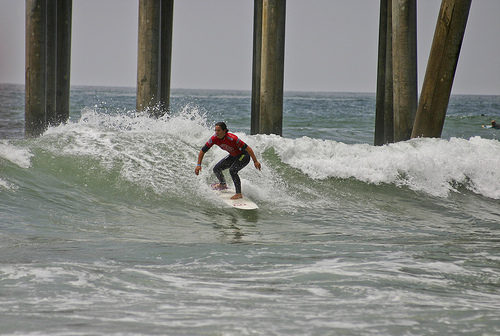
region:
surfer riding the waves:
[8, 8, 470, 298]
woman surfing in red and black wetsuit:
[164, 80, 299, 247]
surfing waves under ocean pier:
[27, 42, 469, 257]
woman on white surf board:
[185, 100, 270, 235]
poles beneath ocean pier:
[1, 5, 491, 240]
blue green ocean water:
[15, 226, 450, 331]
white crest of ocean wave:
[22, 46, 379, 261]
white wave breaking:
[345, 40, 487, 170]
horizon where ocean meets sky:
[6, 41, 496, 212]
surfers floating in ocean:
[448, 80, 499, 172]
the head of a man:
[210, 117, 230, 140]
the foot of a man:
[227, 187, 245, 200]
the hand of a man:
[248, 157, 263, 173]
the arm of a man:
[188, 134, 218, 178]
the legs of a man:
[208, 149, 253, 203]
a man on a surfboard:
[184, 118, 263, 202]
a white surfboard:
[200, 178, 260, 218]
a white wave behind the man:
[1, 102, 498, 212]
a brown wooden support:
[131, 0, 178, 130]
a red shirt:
[202, 130, 254, 162]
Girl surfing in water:
[182, 103, 290, 227]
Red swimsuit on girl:
[196, 132, 262, 173]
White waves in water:
[288, 138, 416, 211]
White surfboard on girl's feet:
[203, 176, 259, 234]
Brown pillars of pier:
[0, 3, 491, 110]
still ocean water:
[103, 239, 387, 334]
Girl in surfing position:
[191, 117, 269, 215]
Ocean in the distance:
[173, 28, 245, 130]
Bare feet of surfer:
[208, 171, 251, 209]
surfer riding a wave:
[163, 109, 300, 228]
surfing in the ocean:
[18, 13, 465, 260]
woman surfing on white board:
[172, 87, 288, 244]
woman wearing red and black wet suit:
[191, 112, 291, 238]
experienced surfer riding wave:
[182, 95, 270, 222]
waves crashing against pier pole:
[15, 27, 180, 204]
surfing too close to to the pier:
[21, 30, 361, 182]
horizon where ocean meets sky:
[103, 27, 347, 124]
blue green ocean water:
[104, 244, 338, 323]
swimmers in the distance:
[457, 93, 498, 146]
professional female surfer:
[171, 103, 312, 230]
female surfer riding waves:
[191, 116, 271, 221]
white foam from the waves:
[54, 103, 201, 140]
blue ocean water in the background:
[297, 88, 369, 133]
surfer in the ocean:
[472, 114, 499, 139]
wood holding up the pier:
[9, 6, 474, 63]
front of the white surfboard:
[220, 200, 268, 217]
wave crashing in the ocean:
[268, 127, 498, 207]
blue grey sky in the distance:
[292, 5, 374, 82]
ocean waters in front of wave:
[30, 261, 479, 323]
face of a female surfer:
[208, 121, 234, 142]